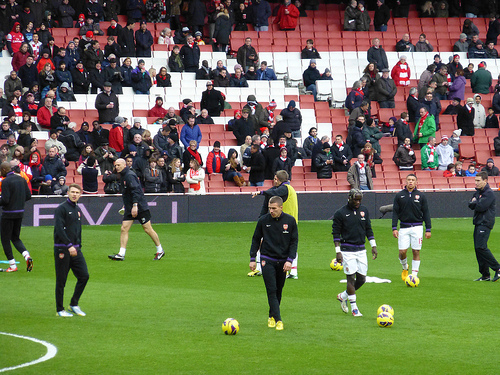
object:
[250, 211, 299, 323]
warm ups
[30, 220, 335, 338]
grass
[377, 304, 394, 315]
ball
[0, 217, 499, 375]
field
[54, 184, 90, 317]
players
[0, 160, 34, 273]
players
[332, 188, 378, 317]
players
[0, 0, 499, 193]
seats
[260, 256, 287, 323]
pants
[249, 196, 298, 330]
man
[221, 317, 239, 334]
ball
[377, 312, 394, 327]
ball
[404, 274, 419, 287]
ball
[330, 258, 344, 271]
ball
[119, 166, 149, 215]
jacket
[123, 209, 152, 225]
shorts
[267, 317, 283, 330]
shoes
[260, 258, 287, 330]
feet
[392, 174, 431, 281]
man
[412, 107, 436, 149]
man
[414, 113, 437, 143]
jacket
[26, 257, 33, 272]
cleats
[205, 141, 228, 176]
person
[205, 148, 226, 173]
jacket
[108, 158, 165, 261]
man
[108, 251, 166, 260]
shoes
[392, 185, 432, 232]
jacket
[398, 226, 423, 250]
shorts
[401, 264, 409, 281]
shoes